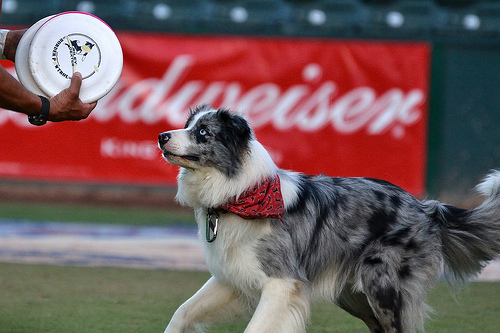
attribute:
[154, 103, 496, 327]
dog — black, white, gray, waiting, small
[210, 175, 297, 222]
scarf — red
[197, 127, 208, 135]
eye — blue, open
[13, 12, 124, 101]
frisbie — white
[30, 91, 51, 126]
watch — black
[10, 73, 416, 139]
budweiser — white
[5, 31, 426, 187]
sign — red, white, large, hidden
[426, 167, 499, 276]
tail — fluffy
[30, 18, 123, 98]
frisbee — white, round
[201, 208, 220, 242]
lock — green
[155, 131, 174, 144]
nose — black